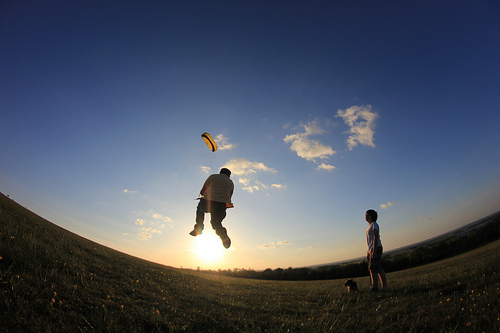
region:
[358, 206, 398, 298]
a woman is standing in a field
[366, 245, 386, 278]
the woman is wearing capris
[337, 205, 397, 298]
a little dog is at her feet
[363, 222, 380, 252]
the lady has a white t-shirt on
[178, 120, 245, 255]
the man is flying a kite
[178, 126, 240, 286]
the kite has pulled the person off the ground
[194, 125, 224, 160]
the kite is yellow and black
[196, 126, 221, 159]
the shape of the kite is used in wind surfing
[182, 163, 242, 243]
the man is holding onto a harness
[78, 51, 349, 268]
the sun is up and glaring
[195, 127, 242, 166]
this is a kite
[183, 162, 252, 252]
this person is airborne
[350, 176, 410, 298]
this is a kid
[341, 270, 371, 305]
this is a dog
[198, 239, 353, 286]
these are green trees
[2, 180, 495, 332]
this is a field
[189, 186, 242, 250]
these are blue jeans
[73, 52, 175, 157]
this is the sky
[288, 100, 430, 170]
these are white clouds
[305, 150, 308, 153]
this is the color white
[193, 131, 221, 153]
A yellow and black kite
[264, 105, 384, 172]
A cloud in the sky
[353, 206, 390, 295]
A man standing watch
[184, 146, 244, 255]
A man jumping off ground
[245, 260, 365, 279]
A line of trees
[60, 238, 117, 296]
A field of grass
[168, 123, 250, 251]
A man flying a kite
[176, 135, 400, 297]
A group of people flying a kite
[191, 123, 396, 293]
A group of people outdoors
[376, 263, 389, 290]
A persons right leg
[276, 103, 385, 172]
clouds are in the sky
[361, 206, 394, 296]
the boy standing in field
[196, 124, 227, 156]
kite flying in air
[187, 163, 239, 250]
the man in the air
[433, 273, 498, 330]
THE LITTLE YELLOW FLOWERS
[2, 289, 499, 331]
grass is everywhere in the field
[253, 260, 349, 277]
trees are in background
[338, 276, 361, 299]
a dog in grass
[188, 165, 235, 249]
the man has white shirt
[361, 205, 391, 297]
the boy has on white shirt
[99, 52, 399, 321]
the sky is bright and blue